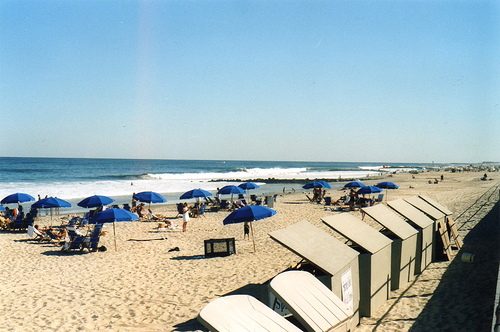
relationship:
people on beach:
[194, 196, 244, 215] [5, 162, 466, 330]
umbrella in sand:
[93, 208, 143, 243] [102, 240, 179, 295]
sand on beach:
[102, 240, 179, 295] [5, 162, 466, 330]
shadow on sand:
[365, 177, 499, 328] [102, 240, 179, 295]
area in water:
[214, 176, 315, 187] [1, 159, 434, 195]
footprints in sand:
[199, 244, 268, 307] [102, 240, 179, 295]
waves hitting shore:
[136, 162, 289, 180] [32, 171, 398, 207]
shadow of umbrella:
[168, 251, 214, 266] [216, 202, 280, 253]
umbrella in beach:
[93, 208, 143, 243] [5, 162, 466, 330]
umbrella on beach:
[93, 208, 143, 243] [5, 162, 466, 330]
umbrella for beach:
[93, 208, 143, 243] [5, 162, 466, 330]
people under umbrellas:
[194, 196, 244, 215] [179, 179, 260, 202]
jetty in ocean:
[211, 174, 311, 187] [1, 155, 433, 200]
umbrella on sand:
[93, 208, 143, 243] [102, 240, 179, 295]